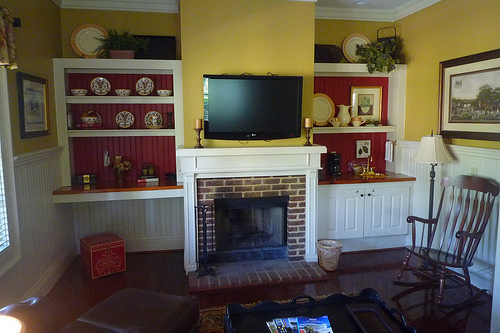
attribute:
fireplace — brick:
[192, 170, 308, 270]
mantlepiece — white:
[172, 140, 333, 294]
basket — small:
[355, 26, 425, 73]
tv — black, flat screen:
[201, 73, 301, 138]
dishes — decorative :
[62, 67, 181, 132]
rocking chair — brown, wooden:
[389, 173, 498, 311]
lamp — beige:
[412, 128, 457, 250]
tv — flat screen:
[199, 71, 305, 143]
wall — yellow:
[177, 0, 317, 190]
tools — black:
[194, 200, 221, 277]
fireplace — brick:
[185, 168, 312, 280]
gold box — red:
[62, 220, 163, 281]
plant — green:
[354, 25, 409, 78]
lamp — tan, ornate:
[387, 102, 488, 328]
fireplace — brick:
[193, 174, 303, 268]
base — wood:
[426, 159, 436, 252]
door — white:
[317, 187, 365, 240]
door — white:
[363, 185, 411, 238]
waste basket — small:
[317, 235, 345, 273]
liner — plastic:
[312, 235, 343, 255]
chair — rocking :
[404, 176, 485, 298]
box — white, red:
[80, 231, 130, 279]